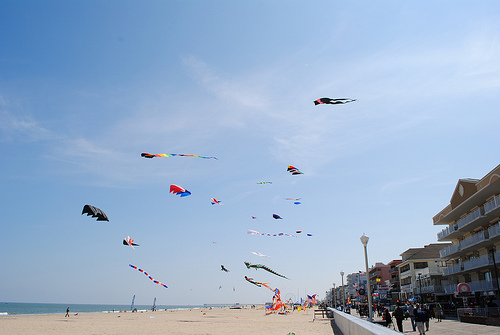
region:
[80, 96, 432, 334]
Several people flying kites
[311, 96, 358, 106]
Black kite with stripe flying in air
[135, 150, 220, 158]
Long multi-color kite flying in air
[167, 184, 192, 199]
Yellow, red and blue kite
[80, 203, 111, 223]
Black kite flying in air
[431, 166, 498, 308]
Large brown apartment building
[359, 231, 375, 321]
Tall white street light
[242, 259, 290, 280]
Long gray kite flying in the air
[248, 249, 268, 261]
White kite flying in the air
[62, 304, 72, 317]
Person walking on the beach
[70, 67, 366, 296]
many kite sin the sky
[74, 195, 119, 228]
a black kite in the sky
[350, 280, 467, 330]
a group of people in front a building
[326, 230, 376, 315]
lights in front buildings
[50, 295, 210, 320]
people in the beach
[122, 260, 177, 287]
a kite like a snake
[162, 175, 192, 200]
a kite color blue, yellow and red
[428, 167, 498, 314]
a five floor building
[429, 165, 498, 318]
building has balconies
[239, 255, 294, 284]
a long kite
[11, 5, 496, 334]
Picture taken outdoors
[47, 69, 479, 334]
picture taken during the day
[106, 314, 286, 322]
a beach setting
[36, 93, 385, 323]
many kites in the sky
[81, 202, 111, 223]
the kite is black.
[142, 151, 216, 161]
this kite is rainbow.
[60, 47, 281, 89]
whispey clouds inthe sky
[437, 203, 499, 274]
an apartment building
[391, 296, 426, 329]
people walking on the sidewalk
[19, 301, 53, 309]
the ocean next to the sand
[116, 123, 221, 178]
multi colored kite in sky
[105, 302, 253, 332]
sand on the beach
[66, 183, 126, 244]
black kite in the sky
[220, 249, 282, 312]
kites in the background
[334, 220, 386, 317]
long tall light pole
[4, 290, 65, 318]
waters of the ocean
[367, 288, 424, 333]
people on the boardwalk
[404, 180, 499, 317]
condo by the beach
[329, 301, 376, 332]
rail splitting boardwalk and beach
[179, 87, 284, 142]
white clouds in the sky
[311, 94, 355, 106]
a kite in flight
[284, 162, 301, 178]
a kite in flight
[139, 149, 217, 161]
a kite in flight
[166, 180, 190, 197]
a kite in flight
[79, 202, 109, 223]
a kite in flight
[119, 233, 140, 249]
a kite in flight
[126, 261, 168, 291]
a kite in flight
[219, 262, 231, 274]
a kite in flight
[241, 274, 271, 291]
a kite in flight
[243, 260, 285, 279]
a kite in flight